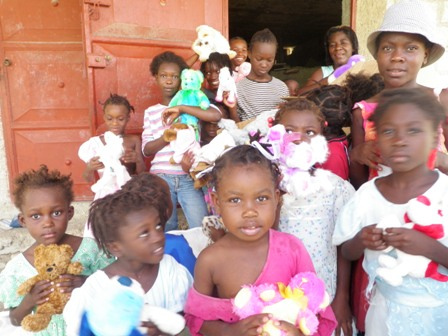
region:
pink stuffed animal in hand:
[227, 259, 328, 323]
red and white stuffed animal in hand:
[367, 193, 445, 283]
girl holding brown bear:
[0, 166, 97, 318]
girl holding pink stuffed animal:
[193, 148, 335, 331]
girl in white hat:
[362, 3, 445, 96]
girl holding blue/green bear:
[147, 48, 215, 218]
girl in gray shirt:
[234, 27, 292, 116]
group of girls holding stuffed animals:
[8, 27, 445, 335]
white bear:
[80, 132, 126, 193]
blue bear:
[75, 263, 153, 334]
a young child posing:
[189, 144, 336, 334]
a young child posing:
[68, 190, 194, 334]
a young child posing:
[2, 169, 117, 334]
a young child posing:
[79, 93, 141, 196]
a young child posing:
[335, 87, 447, 333]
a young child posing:
[251, 95, 355, 334]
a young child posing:
[235, 26, 287, 116]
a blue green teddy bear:
[169, 68, 209, 124]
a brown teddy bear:
[17, 242, 78, 332]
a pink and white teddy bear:
[233, 271, 327, 334]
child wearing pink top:
[182, 150, 336, 333]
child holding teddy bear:
[4, 160, 86, 325]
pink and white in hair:
[177, 103, 328, 244]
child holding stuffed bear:
[140, 45, 221, 224]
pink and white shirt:
[132, 101, 203, 208]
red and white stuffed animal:
[368, 182, 445, 282]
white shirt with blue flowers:
[288, 191, 364, 272]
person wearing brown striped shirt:
[237, 24, 293, 122]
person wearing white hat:
[367, 2, 443, 88]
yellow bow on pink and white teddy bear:
[253, 267, 350, 331]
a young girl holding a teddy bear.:
[175, 110, 350, 334]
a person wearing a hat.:
[361, 0, 443, 119]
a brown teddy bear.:
[13, 217, 88, 335]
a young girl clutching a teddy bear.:
[4, 152, 113, 335]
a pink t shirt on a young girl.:
[175, 223, 338, 333]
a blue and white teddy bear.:
[87, 267, 164, 332]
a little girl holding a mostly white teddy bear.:
[253, 94, 365, 329]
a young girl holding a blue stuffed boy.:
[64, 182, 201, 334]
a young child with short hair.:
[217, 18, 304, 140]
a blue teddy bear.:
[171, 57, 217, 145]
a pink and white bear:
[215, 273, 332, 334]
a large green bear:
[168, 65, 206, 125]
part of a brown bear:
[12, 238, 81, 330]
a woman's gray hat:
[364, 0, 444, 70]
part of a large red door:
[76, 2, 233, 179]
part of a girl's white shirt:
[333, 165, 446, 287]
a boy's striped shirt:
[234, 76, 292, 117]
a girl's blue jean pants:
[158, 171, 213, 227]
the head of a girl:
[208, 143, 283, 239]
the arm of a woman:
[302, 69, 326, 97]